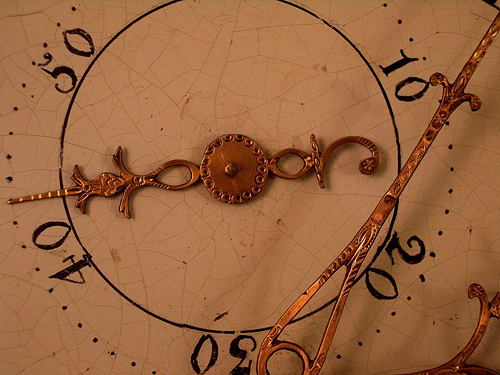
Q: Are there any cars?
A: No, there are no cars.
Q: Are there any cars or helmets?
A: No, there are no cars or helmets.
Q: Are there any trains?
A: No, there are no trains.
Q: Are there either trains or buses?
A: No, there are no trains or buses.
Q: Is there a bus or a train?
A: No, there are no trains or buses.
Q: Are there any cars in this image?
A: No, there are no cars.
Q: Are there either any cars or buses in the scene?
A: No, there are no cars or buses.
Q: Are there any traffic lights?
A: No, there are no traffic lights.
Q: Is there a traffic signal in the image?
A: No, there are no traffic lights.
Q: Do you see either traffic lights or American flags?
A: No, there are no traffic lights or American flags.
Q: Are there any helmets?
A: No, there are no helmets.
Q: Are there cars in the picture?
A: No, there are no cars.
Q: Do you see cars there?
A: No, there are no cars.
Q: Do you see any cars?
A: No, there are no cars.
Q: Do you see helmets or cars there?
A: No, there are no cars or helmets.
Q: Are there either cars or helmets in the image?
A: No, there are no cars or helmets.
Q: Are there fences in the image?
A: No, there are no fences.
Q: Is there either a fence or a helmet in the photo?
A: No, there are no fences or helmets.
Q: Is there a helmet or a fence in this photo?
A: No, there are no fences or helmets.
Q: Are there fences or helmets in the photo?
A: No, there are no fences or helmets.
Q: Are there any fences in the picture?
A: No, there are no fences.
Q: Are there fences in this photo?
A: No, there are no fences.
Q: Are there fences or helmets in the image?
A: No, there are no fences or helmets.